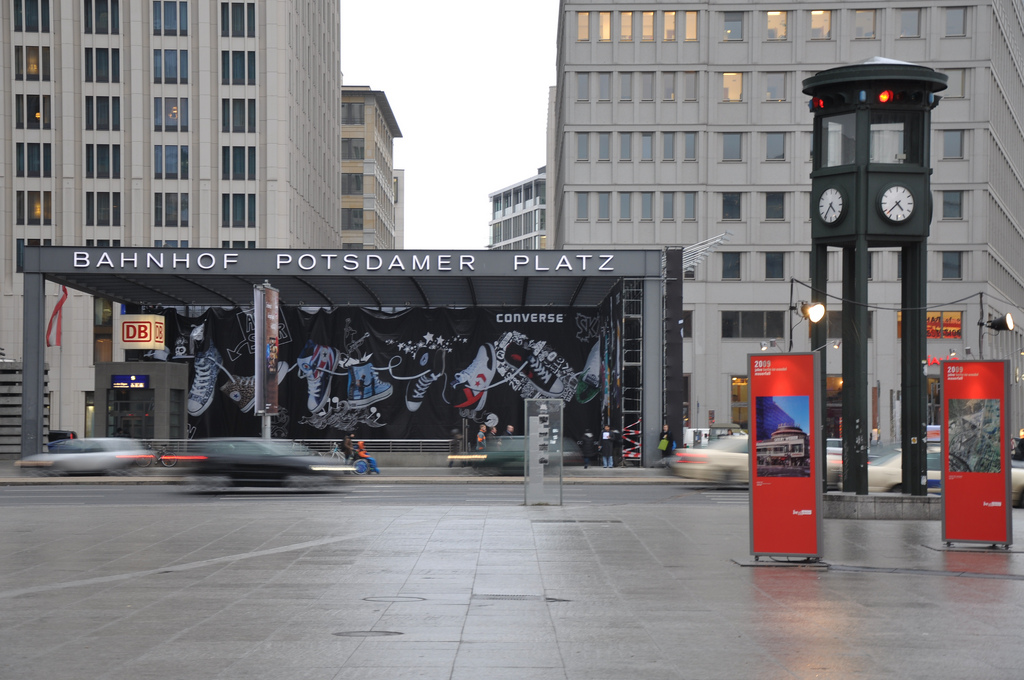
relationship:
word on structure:
[60, 230, 653, 310] [16, 238, 684, 461]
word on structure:
[69, 247, 617, 275] [16, 238, 684, 461]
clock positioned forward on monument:
[879, 190, 911, 217] [794, 26, 985, 506]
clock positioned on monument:
[813, 181, 843, 221] [794, 50, 944, 521]